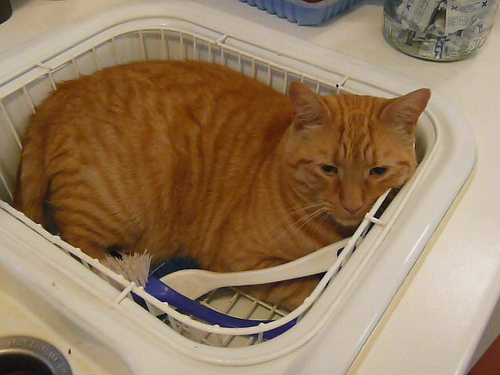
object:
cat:
[17, 60, 428, 310]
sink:
[2, 0, 475, 374]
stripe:
[335, 95, 345, 139]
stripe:
[279, 177, 331, 244]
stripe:
[93, 160, 127, 210]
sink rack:
[2, 18, 439, 349]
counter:
[0, 0, 500, 375]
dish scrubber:
[112, 250, 296, 339]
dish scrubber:
[143, 237, 356, 317]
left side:
[0, 0, 141, 375]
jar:
[379, 2, 493, 62]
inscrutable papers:
[445, 6, 474, 33]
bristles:
[94, 254, 148, 288]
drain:
[0, 331, 73, 373]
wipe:
[446, 8, 468, 36]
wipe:
[394, 0, 440, 33]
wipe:
[476, 12, 492, 31]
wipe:
[399, 28, 416, 46]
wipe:
[419, 39, 443, 59]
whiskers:
[275, 202, 327, 227]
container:
[232, 0, 364, 25]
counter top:
[1, 0, 499, 373]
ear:
[382, 88, 432, 125]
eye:
[369, 167, 386, 176]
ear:
[290, 81, 331, 129]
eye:
[322, 166, 338, 173]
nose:
[341, 201, 364, 213]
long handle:
[217, 236, 353, 289]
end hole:
[337, 247, 356, 256]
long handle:
[153, 281, 296, 339]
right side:
[328, 1, 499, 375]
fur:
[84, 87, 191, 199]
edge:
[286, 1, 331, 25]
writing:
[11, 340, 59, 361]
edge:
[451, 285, 500, 374]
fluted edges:
[286, 111, 478, 374]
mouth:
[336, 215, 362, 221]